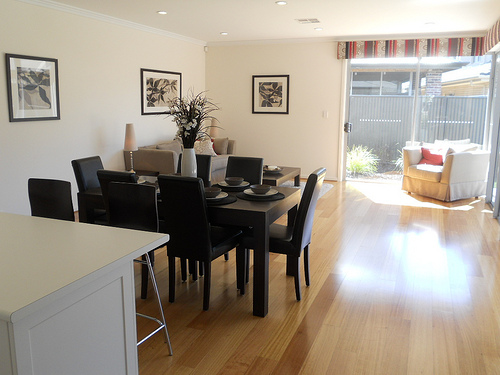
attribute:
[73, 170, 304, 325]
table — black, dark, wooden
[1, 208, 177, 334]
counter — white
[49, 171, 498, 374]
floor — wooden, brown, hardwood, shiny, wood, glossy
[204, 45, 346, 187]
wall — clean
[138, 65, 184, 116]
picture — black, white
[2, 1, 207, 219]
wall — clean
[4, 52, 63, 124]
picture — black, white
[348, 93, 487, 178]
fence — wooden, dividing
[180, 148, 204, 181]
vase — white, tall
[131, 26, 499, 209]
living space — airy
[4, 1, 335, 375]
dining space — airy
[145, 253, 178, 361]
leg — metal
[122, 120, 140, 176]
lamp — narrow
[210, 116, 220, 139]
lamp — narrow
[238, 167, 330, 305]
chair — dark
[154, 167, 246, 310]
chair — dark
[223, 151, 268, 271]
chair — dark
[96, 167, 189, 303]
chair — dark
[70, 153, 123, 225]
chair — dark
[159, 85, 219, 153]
flower arrangement — large, pretty, black, white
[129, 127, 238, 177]
couch — tan, white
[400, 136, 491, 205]
chair — large, cushioned, white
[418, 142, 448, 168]
pillow — red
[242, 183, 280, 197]
china setting — contemporary, black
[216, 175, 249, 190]
china setting — contemporary, black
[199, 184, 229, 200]
china setting — cont, black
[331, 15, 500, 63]
valence — striped